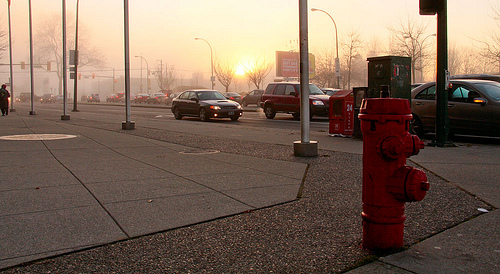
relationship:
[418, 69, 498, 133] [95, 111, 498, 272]
car by sidewalk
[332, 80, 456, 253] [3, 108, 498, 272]
hydrant on sidewalk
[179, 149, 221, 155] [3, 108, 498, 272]
cover in sidewalk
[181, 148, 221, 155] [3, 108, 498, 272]
cover in sidewalk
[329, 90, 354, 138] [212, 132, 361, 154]
newspaper stand on sidewalk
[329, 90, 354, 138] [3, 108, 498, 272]
newspaper stand on sidewalk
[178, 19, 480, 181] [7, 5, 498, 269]
cars in city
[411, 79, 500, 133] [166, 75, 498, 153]
car carrying people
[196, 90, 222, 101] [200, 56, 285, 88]
people at sundown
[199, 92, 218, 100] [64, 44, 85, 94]
people obeying laws